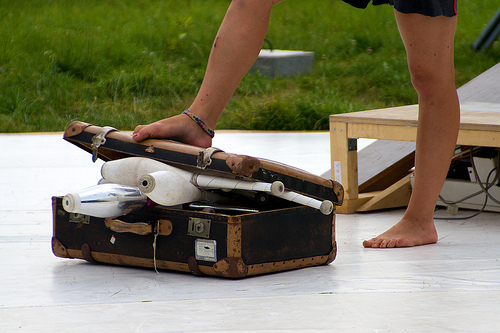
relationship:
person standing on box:
[131, 0, 461, 249] [49, 119, 346, 278]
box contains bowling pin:
[69, 123, 377, 275] [100, 156, 285, 196]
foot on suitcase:
[131, 112, 214, 148] [51, 120, 345, 280]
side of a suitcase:
[234, 200, 336, 275] [51, 120, 345, 280]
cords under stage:
[446, 162, 496, 229] [325, 102, 498, 216]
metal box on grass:
[248, 35, 317, 80] [0, 0, 500, 135]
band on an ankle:
[181, 107, 216, 136] [167, 97, 221, 141]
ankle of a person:
[167, 97, 221, 141] [131, 0, 461, 249]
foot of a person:
[134, 112, 214, 148] [131, 0, 461, 249]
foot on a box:
[134, 112, 214, 148] [49, 119, 345, 279]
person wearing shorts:
[190, 4, 455, 237] [335, 1, 462, 15]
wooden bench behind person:
[330, 100, 499, 213] [131, 0, 461, 249]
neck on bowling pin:
[190, 172, 267, 194] [101, 157, 285, 194]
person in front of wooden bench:
[131, 0, 461, 249] [327, 100, 500, 214]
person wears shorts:
[131, 0, 461, 249] [344, 1, 476, 25]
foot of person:
[336, 194, 456, 262] [101, 7, 487, 254]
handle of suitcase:
[95, 213, 163, 243] [43, 110, 353, 306]